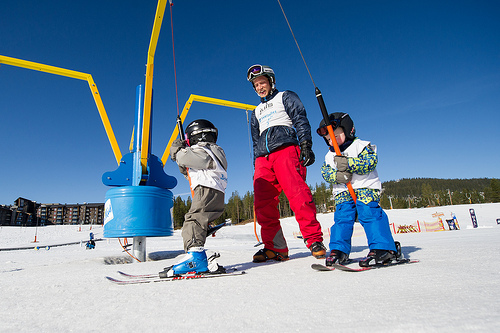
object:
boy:
[166, 119, 229, 280]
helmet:
[316, 112, 355, 150]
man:
[243, 63, 326, 261]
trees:
[165, 180, 417, 219]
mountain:
[170, 176, 499, 228]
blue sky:
[2, 1, 500, 200]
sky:
[0, 0, 499, 205]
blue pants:
[331, 188, 398, 253]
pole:
[161, 3, 201, 201]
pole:
[140, 0, 170, 170]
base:
[102, 84, 177, 261]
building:
[0, 196, 104, 227]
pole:
[0, 54, 124, 166]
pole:
[176, 115, 193, 200]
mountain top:
[0, 202, 500, 333]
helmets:
[246, 64, 275, 97]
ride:
[0, 0, 313, 263]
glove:
[299, 139, 316, 166]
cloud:
[0, 92, 500, 191]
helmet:
[185, 118, 218, 142]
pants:
[249, 141, 330, 246]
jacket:
[250, 90, 313, 169]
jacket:
[322, 140, 380, 205]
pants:
[182, 186, 225, 249]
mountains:
[381, 176, 500, 210]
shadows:
[339, 244, 421, 268]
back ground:
[0, 177, 499, 224]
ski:
[115, 268, 166, 281]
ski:
[104, 270, 246, 285]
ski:
[310, 259, 358, 271]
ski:
[334, 259, 418, 272]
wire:
[165, 4, 180, 122]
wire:
[275, 3, 318, 92]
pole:
[314, 89, 359, 203]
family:
[157, 64, 400, 277]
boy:
[317, 112, 403, 266]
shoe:
[252, 245, 288, 263]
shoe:
[309, 240, 325, 257]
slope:
[0, 201, 498, 331]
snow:
[2, 199, 498, 328]